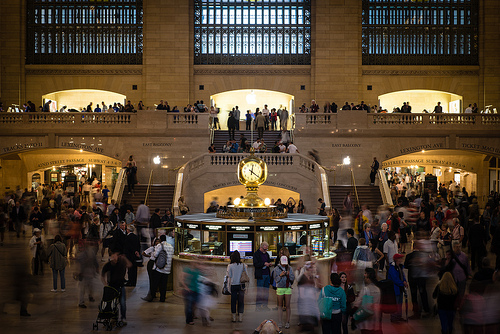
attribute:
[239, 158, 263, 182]
clock — shiny, white, round, gold, lit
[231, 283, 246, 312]
pants — black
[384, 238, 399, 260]
shirt — light, bright, grey, white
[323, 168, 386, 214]
staircase — large, brown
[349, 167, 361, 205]
rail — gold, shiny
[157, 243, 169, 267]
backpack — grey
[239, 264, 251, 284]
bag — tan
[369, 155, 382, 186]
person — standing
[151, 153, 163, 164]
light — hanging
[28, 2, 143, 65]
window — large, square, covered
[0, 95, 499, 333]
people — scattered